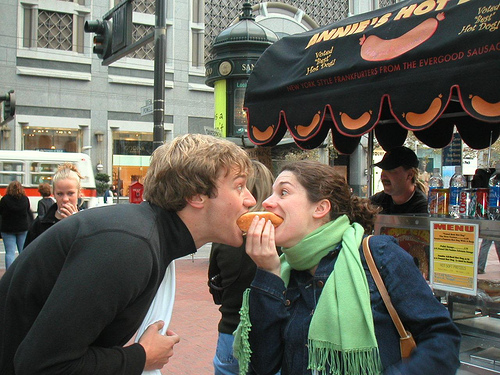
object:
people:
[36, 181, 57, 216]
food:
[237, 211, 284, 232]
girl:
[245, 158, 460, 374]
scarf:
[232, 214, 380, 373]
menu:
[429, 221, 479, 297]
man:
[369, 147, 428, 213]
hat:
[368, 144, 418, 169]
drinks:
[435, 188, 449, 217]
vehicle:
[1, 150, 94, 212]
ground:
[0, 257, 222, 374]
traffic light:
[83, 18, 105, 55]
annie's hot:
[305, 0, 447, 46]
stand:
[244, 0, 500, 374]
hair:
[279, 160, 384, 234]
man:
[1, 133, 255, 373]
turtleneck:
[1, 200, 198, 374]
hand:
[245, 214, 281, 270]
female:
[22, 169, 95, 251]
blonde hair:
[50, 169, 81, 196]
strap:
[362, 233, 409, 339]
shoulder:
[358, 229, 404, 278]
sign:
[112, 140, 153, 157]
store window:
[113, 130, 166, 198]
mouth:
[271, 214, 284, 230]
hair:
[145, 133, 253, 207]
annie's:
[305, 12, 391, 47]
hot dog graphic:
[359, 11, 445, 61]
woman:
[1, 180, 32, 270]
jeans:
[0, 232, 27, 272]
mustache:
[381, 179, 391, 183]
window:
[382, 228, 500, 343]